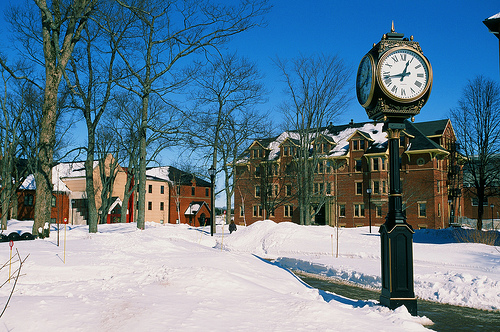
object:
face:
[379, 52, 427, 98]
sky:
[0, 0, 499, 208]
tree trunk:
[137, 80, 147, 230]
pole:
[376, 118, 417, 317]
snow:
[0, 219, 499, 331]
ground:
[0, 218, 499, 331]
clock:
[374, 45, 432, 104]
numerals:
[398, 88, 406, 99]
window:
[146, 183, 154, 195]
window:
[158, 202, 165, 212]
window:
[145, 201, 151, 210]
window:
[159, 186, 164, 196]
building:
[132, 165, 214, 227]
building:
[230, 117, 462, 233]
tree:
[441, 73, 500, 228]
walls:
[230, 141, 436, 228]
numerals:
[412, 79, 424, 89]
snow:
[263, 120, 386, 160]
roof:
[148, 166, 211, 187]